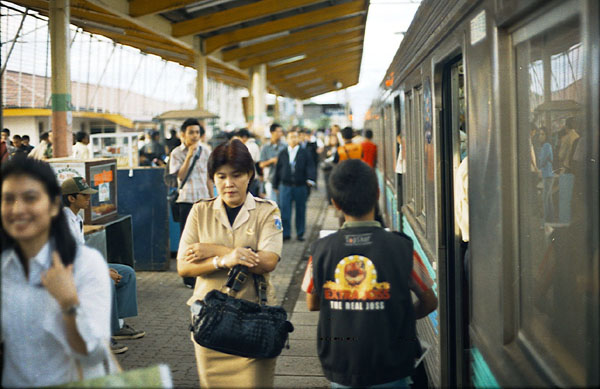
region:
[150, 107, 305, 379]
A woman holding a black bag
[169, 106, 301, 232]
Woman has black hair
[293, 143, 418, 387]
Boy has black vest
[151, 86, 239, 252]
Man wearing plaid shirt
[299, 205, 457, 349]
Yellow circle on black vest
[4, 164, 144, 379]
Woman is wearing white shirt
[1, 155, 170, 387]
a woman is walking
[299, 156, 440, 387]
a boy is walking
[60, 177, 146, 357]
a man is sitting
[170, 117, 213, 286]
a man is walking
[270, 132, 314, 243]
a man is walking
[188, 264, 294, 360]
the purse is black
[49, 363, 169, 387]
green and white bag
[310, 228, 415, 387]
the shirt is black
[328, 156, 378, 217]
the hair is black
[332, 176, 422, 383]
the person is standing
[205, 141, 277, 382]
the person is standing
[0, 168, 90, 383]
the person is standing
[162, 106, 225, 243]
the person is standing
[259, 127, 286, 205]
the person is standing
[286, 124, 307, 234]
the person is standing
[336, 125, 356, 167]
the person is standing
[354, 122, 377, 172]
the person is standing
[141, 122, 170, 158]
the person is standing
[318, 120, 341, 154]
the person is standing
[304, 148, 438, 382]
A person is standing up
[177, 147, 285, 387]
A person is standing up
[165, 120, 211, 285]
A person is standing up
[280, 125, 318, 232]
A person is standing up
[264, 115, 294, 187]
A person is standing up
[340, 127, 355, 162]
A person is standing up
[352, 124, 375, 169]
A person is standing up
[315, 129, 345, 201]
A person is standing up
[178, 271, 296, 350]
the womans hips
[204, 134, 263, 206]
the womans head above shoulders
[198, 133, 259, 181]
the hair on the womans head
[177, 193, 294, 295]
the womans shirt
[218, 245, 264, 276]
the womans hand at end of arm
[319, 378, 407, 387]
the childs legs below torso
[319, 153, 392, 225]
the childs head above shoulders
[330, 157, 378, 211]
the hair on the childs head